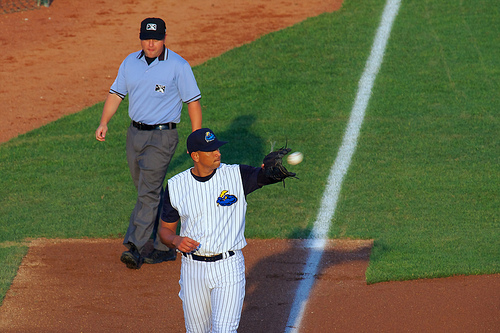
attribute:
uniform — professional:
[166, 172, 248, 326]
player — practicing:
[108, 117, 324, 329]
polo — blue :
[109, 46, 201, 123]